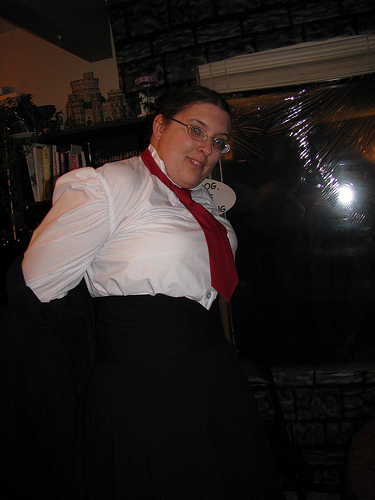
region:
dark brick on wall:
[341, 388, 370, 419]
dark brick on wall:
[292, 390, 340, 417]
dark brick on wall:
[294, 419, 322, 440]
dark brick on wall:
[321, 419, 348, 438]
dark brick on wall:
[299, 443, 342, 466]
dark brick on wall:
[310, 463, 340, 483]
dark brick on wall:
[254, 385, 297, 421]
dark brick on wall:
[151, 26, 196, 50]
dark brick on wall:
[119, 36, 148, 57]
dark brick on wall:
[161, 50, 204, 80]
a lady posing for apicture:
[54, 119, 254, 406]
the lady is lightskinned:
[145, 109, 230, 184]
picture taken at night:
[86, 108, 324, 397]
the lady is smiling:
[96, 76, 261, 338]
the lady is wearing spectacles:
[104, 104, 245, 314]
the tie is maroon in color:
[128, 144, 256, 314]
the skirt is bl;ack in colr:
[106, 308, 200, 471]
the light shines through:
[305, 154, 373, 245]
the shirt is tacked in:
[84, 224, 199, 339]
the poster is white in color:
[205, 171, 243, 214]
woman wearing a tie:
[15, 72, 262, 479]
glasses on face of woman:
[159, 105, 229, 155]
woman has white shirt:
[10, 70, 256, 317]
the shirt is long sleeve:
[8, 150, 244, 315]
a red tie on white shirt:
[135, 145, 244, 303]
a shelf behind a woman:
[6, 117, 148, 262]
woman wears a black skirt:
[16, 69, 259, 485]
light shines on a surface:
[323, 175, 365, 217]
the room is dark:
[10, 1, 373, 491]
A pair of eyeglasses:
[150, 105, 233, 161]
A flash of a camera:
[325, 175, 359, 214]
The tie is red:
[135, 139, 243, 307]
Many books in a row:
[12, 129, 97, 204]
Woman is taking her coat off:
[1, 77, 242, 411]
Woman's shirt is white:
[17, 137, 236, 313]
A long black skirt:
[70, 289, 286, 493]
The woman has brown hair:
[137, 76, 232, 187]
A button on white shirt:
[197, 283, 215, 304]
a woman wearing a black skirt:
[100, 297, 266, 414]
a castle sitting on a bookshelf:
[62, 77, 124, 145]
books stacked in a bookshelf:
[24, 159, 114, 170]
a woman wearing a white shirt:
[44, 156, 184, 304]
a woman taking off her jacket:
[9, 254, 92, 357]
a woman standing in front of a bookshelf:
[124, 105, 252, 386]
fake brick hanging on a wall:
[106, 26, 211, 66]